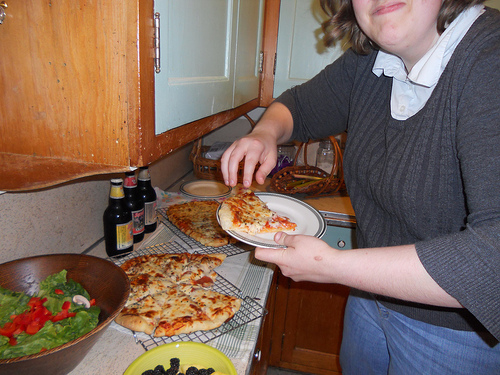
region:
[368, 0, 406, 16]
pink lips on the woman's face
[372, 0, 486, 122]
white dress shirt under the gray sweater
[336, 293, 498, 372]
woman wearing blue jeans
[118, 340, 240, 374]
yellow bowl on the counter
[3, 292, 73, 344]
red tomatoes in the salad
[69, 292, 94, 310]
white mushroom in the salad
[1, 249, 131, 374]
green salad in a brown bowl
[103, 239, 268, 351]
silver metal cooling rack under the pizza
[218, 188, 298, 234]
slice of pizza on the white plate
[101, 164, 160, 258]
beers on the counter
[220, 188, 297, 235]
A slice of pizza.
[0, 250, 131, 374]
A bowl of salad.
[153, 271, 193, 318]
Part of a pizza.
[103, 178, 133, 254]
A dark colored bottle.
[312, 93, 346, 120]
Part of the woman's grey shirt.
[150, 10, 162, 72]
A hinge on the cabnet.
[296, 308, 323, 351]
Part of the brown door.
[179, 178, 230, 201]
A small white plate.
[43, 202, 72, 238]
Part of the wall.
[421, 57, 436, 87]
Part of a white collar.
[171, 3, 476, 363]
woman holding a plate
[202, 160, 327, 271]
pizza on a plate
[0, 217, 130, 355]
a bowl on the counter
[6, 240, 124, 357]
salad in the bowl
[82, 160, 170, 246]
three bottles on the counter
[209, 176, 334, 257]
the plate is white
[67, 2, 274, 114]
the cabinet is brown and white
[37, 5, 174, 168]
the side of the cabinet is made of wood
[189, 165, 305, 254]
the pizza is cheesy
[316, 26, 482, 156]
the shirt is white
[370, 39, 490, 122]
Her shirt is white.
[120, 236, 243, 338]
The pizza is on the table.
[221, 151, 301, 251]
The slice is on the pizza.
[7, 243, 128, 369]
The salad is in the bowl.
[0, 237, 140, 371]
The bowl is brown.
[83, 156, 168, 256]
The bottles are on the table.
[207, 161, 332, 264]
The plate is white.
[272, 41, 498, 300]
Her shirt is gray.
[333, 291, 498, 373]
Her pants are jeans.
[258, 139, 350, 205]
The basket is brown.